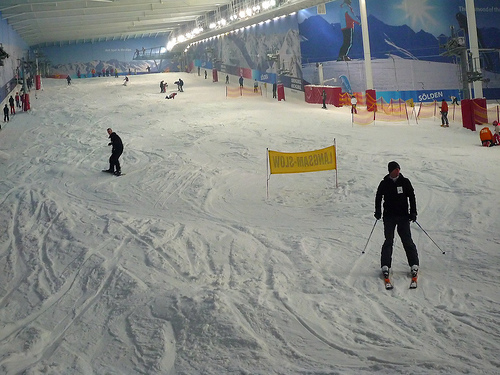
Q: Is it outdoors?
A: Yes, it is outdoors.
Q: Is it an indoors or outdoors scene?
A: It is outdoors.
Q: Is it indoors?
A: No, it is outdoors.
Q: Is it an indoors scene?
A: No, it is outdoors.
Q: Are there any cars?
A: No, there are no cars.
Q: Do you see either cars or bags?
A: No, there are no cars or bags.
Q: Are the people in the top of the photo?
A: Yes, the people are in the top of the image.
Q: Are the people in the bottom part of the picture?
A: No, the people are in the top of the image.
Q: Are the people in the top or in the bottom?
A: The people are in the top of the image.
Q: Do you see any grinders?
A: No, there are no grinders.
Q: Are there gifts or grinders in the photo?
A: No, there are no grinders or gifts.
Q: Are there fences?
A: Yes, there is a fence.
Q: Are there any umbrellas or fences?
A: Yes, there is a fence.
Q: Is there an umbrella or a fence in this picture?
A: Yes, there is a fence.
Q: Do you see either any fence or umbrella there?
A: Yes, there is a fence.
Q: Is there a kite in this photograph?
A: No, there are no kites.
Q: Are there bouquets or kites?
A: No, there are no kites or bouquets.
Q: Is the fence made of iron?
A: No, the fence is made of mesh.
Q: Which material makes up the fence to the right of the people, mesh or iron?
A: The fence is made of mesh.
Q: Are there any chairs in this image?
A: No, there are no chairs.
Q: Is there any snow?
A: Yes, there is snow.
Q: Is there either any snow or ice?
A: Yes, there is snow.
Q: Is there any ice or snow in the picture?
A: Yes, there is snow.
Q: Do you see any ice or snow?
A: Yes, there is snow.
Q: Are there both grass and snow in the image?
A: No, there is snow but no grass.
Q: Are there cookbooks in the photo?
A: No, there are no cookbooks.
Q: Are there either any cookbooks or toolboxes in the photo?
A: No, there are no cookbooks or toolboxes.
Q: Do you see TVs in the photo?
A: No, there are no tvs.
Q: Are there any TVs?
A: No, there are no tvs.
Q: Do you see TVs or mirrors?
A: No, there are no TVs or mirrors.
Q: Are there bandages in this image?
A: No, there are no bandages.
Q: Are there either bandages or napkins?
A: No, there are no bandages or napkins.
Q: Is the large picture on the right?
A: Yes, the picture is on the right of the image.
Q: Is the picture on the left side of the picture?
A: No, the picture is on the right of the image.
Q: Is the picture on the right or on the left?
A: The picture is on the right of the image.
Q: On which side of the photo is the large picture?
A: The picture is on the right of the image.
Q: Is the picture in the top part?
A: Yes, the picture is in the top of the image.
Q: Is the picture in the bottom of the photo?
A: No, the picture is in the top of the image.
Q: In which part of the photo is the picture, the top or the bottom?
A: The picture is in the top of the image.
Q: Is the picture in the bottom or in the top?
A: The picture is in the top of the image.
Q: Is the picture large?
A: Yes, the picture is large.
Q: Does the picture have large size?
A: Yes, the picture is large.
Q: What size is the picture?
A: The picture is large.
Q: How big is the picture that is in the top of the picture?
A: The picture is large.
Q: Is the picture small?
A: No, the picture is large.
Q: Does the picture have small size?
A: No, the picture is large.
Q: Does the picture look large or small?
A: The picture is large.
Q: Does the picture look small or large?
A: The picture is large.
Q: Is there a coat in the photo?
A: Yes, there is a coat.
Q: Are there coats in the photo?
A: Yes, there is a coat.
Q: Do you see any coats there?
A: Yes, there is a coat.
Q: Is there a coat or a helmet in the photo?
A: Yes, there is a coat.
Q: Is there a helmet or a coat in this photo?
A: Yes, there is a coat.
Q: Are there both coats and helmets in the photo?
A: No, there is a coat but no helmets.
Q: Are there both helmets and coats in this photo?
A: No, there is a coat but no helmets.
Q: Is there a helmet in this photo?
A: No, there are no helmets.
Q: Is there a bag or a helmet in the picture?
A: No, there are no helmets or bags.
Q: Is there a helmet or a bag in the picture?
A: No, there are no helmets or bags.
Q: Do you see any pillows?
A: No, there are no pillows.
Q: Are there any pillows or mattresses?
A: No, there are no pillows or mattresses.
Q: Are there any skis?
A: Yes, there are skis.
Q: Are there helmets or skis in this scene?
A: Yes, there are skis.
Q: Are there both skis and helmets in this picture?
A: No, there are skis but no helmets.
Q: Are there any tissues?
A: No, there are no tissues.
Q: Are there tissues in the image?
A: No, there are no tissues.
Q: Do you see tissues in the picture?
A: No, there are no tissues.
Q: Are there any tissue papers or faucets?
A: No, there are no tissue papers or faucets.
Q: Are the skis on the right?
A: Yes, the skis are on the right of the image.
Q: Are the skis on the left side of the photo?
A: No, the skis are on the right of the image.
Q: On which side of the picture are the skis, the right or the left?
A: The skis are on the right of the image.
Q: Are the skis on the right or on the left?
A: The skis are on the right of the image.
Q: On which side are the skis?
A: The skis are on the right of the image.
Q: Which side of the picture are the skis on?
A: The skis are on the right of the image.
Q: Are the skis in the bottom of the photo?
A: Yes, the skis are in the bottom of the image.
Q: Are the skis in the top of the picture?
A: No, the skis are in the bottom of the image.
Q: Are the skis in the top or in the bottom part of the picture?
A: The skis are in the bottom of the image.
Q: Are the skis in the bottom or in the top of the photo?
A: The skis are in the bottom of the image.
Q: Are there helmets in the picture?
A: No, there are no helmets.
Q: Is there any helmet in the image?
A: No, there are no helmets.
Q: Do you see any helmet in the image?
A: No, there are no helmets.